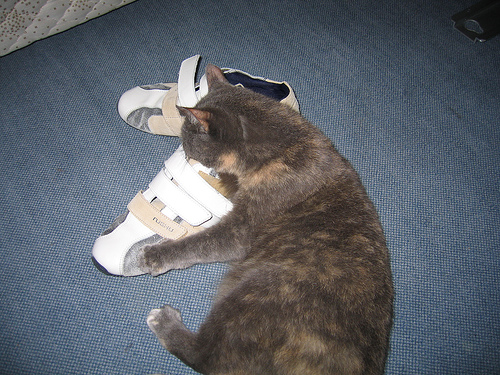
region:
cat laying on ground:
[155, 83, 392, 373]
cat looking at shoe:
[152, 63, 388, 372]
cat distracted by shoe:
[151, 76, 400, 371]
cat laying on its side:
[152, 79, 405, 370]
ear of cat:
[180, 108, 209, 128]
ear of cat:
[204, 68, 220, 83]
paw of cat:
[145, 306, 203, 358]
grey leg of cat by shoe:
[137, 205, 239, 277]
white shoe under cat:
[89, 154, 242, 283]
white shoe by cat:
[120, 68, 298, 140]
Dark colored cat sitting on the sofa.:
[139, 62, 411, 374]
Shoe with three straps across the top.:
[85, 142, 231, 280]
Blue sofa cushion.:
[395, 62, 498, 371]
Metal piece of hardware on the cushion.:
[447, 5, 497, 50]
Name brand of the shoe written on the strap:
[145, 212, 181, 236]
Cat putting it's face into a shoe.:
[80, 45, 426, 374]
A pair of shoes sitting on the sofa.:
[82, 45, 307, 295]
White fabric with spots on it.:
[2, 1, 152, 61]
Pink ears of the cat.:
[170, 62, 244, 148]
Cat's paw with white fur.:
[139, 302, 184, 347]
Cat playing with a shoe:
[61, 10, 438, 346]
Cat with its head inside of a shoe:
[70, 88, 287, 298]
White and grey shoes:
[56, 45, 313, 288]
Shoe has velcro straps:
[56, 106, 226, 277]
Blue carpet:
[11, 15, 485, 363]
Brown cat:
[128, 84, 410, 374]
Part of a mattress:
[0, 0, 155, 71]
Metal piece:
[439, 0, 498, 64]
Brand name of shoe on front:
[146, 198, 193, 249]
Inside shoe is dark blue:
[206, 57, 291, 113]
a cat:
[129, 82, 396, 374]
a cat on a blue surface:
[148, 79, 407, 373]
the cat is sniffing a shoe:
[137, 68, 404, 373]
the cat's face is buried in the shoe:
[136, 64, 399, 373]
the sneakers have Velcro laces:
[88, 44, 300, 279]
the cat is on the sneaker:
[99, 64, 396, 374]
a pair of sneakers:
[83, 43, 401, 279]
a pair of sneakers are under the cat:
[88, 54, 393, 374]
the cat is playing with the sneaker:
[85, 51, 401, 373]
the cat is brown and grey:
[136, 63, 395, 373]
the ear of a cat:
[171, 100, 216, 135]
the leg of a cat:
[135, 210, 245, 282]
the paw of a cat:
[131, 233, 178, 282]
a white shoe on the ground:
[109, 51, 306, 141]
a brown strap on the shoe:
[121, 187, 192, 241]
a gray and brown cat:
[132, 63, 399, 374]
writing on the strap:
[148, 210, 177, 234]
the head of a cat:
[167, 60, 302, 175]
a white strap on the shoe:
[146, 168, 219, 230]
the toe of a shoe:
[111, 81, 137, 118]